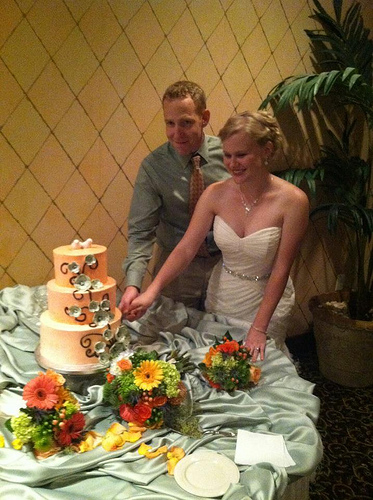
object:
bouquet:
[199, 330, 258, 389]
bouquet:
[103, 347, 199, 439]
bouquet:
[4, 369, 85, 454]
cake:
[35, 231, 126, 377]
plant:
[259, 0, 371, 313]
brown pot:
[311, 291, 371, 383]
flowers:
[90, 347, 191, 427]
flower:
[83, 252, 94, 262]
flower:
[74, 275, 91, 289]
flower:
[87, 300, 95, 310]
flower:
[68, 304, 81, 317]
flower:
[94, 337, 105, 353]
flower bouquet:
[4, 366, 93, 459]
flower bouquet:
[102, 348, 196, 444]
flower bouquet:
[198, 332, 262, 401]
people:
[127, 86, 304, 495]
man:
[117, 81, 238, 312]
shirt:
[120, 134, 233, 287]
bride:
[126, 113, 307, 362]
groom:
[120, 85, 226, 310]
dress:
[206, 212, 294, 350]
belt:
[217, 257, 271, 288]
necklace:
[230, 195, 261, 212]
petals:
[84, 417, 186, 495]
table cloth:
[145, 312, 198, 351]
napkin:
[223, 418, 297, 473]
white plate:
[172, 447, 242, 499]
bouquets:
[5, 327, 268, 458]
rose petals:
[78, 424, 178, 475]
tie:
[183, 152, 208, 261]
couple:
[116, 79, 308, 364]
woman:
[120, 107, 315, 352]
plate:
[33, 339, 122, 374]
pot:
[304, 288, 367, 387]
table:
[1, 282, 323, 498]